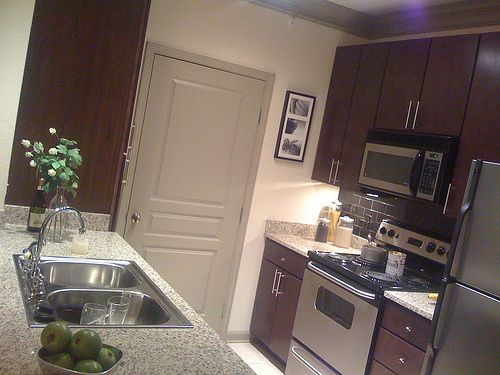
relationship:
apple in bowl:
[40, 320, 72, 354] [34, 345, 125, 374]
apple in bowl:
[70, 329, 105, 356] [34, 345, 125, 374]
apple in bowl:
[96, 347, 119, 369] [34, 345, 125, 374]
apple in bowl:
[73, 359, 104, 373] [34, 345, 125, 374]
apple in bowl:
[45, 353, 74, 368] [34, 345, 125, 374]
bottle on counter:
[27, 175, 49, 229] [1, 224, 255, 374]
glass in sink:
[78, 301, 108, 325] [44, 286, 170, 327]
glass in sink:
[107, 298, 131, 325] [44, 286, 170, 327]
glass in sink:
[120, 288, 144, 324] [44, 286, 170, 327]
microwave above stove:
[356, 126, 460, 205] [286, 224, 454, 374]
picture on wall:
[274, 88, 316, 164] [149, 0, 374, 344]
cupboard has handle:
[375, 35, 478, 134] [404, 101, 412, 130]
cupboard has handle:
[375, 35, 478, 134] [412, 99, 419, 130]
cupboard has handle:
[312, 43, 390, 190] [327, 159, 334, 183]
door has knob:
[118, 39, 277, 340] [129, 212, 144, 225]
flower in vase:
[47, 126, 57, 134] [45, 184, 70, 243]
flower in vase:
[18, 136, 32, 149] [45, 184, 70, 243]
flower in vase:
[46, 166, 56, 178] [45, 184, 70, 243]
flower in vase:
[28, 159, 37, 167] [45, 184, 70, 243]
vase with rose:
[45, 184, 70, 243] [47, 126, 57, 134]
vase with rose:
[45, 184, 70, 243] [46, 166, 56, 178]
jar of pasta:
[326, 197, 345, 244] [329, 210, 342, 243]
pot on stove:
[362, 232, 387, 265] [286, 224, 454, 374]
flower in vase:
[46, 147, 60, 156] [45, 184, 70, 243]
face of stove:
[285, 259, 380, 375] [286, 224, 454, 374]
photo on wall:
[274, 88, 316, 164] [149, 0, 374, 344]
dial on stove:
[378, 226, 388, 236] [286, 224, 454, 374]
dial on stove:
[386, 228, 396, 238] [286, 224, 454, 374]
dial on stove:
[426, 239, 437, 254] [286, 224, 454, 374]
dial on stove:
[436, 244, 446, 256] [286, 224, 454, 374]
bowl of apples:
[34, 345, 125, 374] [37, 322, 116, 371]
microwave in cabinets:
[356, 126, 460, 205] [310, 35, 499, 211]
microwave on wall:
[356, 126, 460, 205] [315, 12, 499, 244]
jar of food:
[326, 197, 345, 244] [329, 210, 342, 243]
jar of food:
[333, 214, 355, 249] [334, 225, 352, 248]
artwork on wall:
[274, 88, 316, 164] [149, 0, 374, 344]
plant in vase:
[20, 127, 85, 198] [45, 184, 70, 243]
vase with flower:
[45, 184, 70, 243] [18, 136, 32, 149]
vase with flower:
[45, 184, 70, 243] [47, 126, 57, 134]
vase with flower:
[45, 184, 70, 243] [28, 159, 37, 167]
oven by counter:
[286, 224, 454, 374] [267, 229, 364, 253]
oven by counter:
[286, 224, 454, 374] [384, 288, 439, 319]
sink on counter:
[44, 286, 170, 327] [1, 224, 255, 374]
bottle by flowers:
[27, 175, 49, 229] [20, 127, 85, 198]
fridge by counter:
[422, 157, 500, 374] [384, 288, 439, 319]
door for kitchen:
[118, 39, 277, 340] [0, 1, 499, 372]